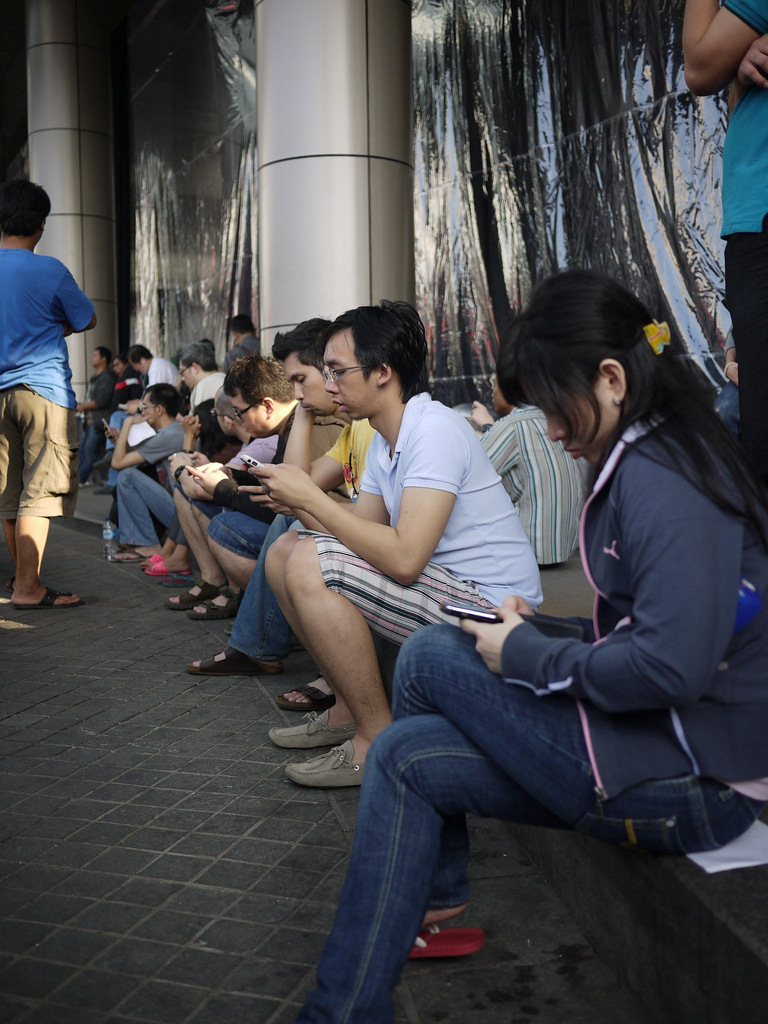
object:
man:
[237, 302, 545, 789]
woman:
[297, 266, 768, 1024]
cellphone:
[440, 602, 500, 624]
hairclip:
[642, 318, 672, 354]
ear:
[595, 358, 626, 408]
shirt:
[358, 391, 546, 607]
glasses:
[321, 365, 365, 382]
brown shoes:
[268, 706, 376, 789]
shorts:
[294, 528, 534, 648]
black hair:
[494, 266, 768, 553]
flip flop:
[403, 918, 488, 957]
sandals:
[165, 578, 243, 621]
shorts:
[0, 384, 79, 518]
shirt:
[0, 247, 97, 409]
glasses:
[232, 402, 260, 426]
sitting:
[111, 265, 766, 865]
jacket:
[495, 403, 768, 827]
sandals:
[186, 638, 335, 710]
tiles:
[0, 618, 307, 1015]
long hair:
[493, 269, 768, 581]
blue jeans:
[291, 625, 762, 1024]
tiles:
[0, 421, 768, 1024]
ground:
[0, 474, 767, 1024]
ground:
[130, 715, 288, 862]